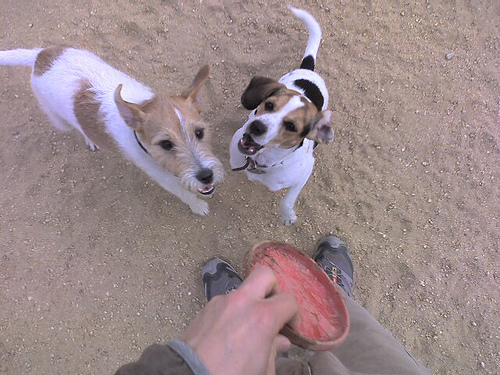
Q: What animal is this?
A: A dog.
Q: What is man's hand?
A: Frisbee.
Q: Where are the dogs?
A: On dirt.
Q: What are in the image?
A: Part of a hand and fingers.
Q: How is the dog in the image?
A: Jumping.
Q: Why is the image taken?
A: Remembrance.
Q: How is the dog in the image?
A: Collar.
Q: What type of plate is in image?
A: Red clay.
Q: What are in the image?
A: Brown dirt and pebbles.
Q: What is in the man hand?
A: Frisbee.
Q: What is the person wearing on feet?
A: Shoes.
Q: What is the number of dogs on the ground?
A: Two.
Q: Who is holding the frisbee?
A: A person.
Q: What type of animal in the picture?
A: Dog.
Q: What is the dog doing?
A: Looking up.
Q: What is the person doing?
A: Standing.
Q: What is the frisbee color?
A: Red.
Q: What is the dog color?
A: Black white and brown.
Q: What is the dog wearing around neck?
A: Collar.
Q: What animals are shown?
A: Dogs.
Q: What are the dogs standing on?
A: Dirt.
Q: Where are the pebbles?
A: In the dirt.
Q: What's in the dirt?
A: Pebbles.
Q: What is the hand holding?
A: The disc.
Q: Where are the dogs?
A: On the ground.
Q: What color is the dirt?
A: Brown.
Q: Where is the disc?
A: In the hand.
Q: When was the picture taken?
A: Daytime.